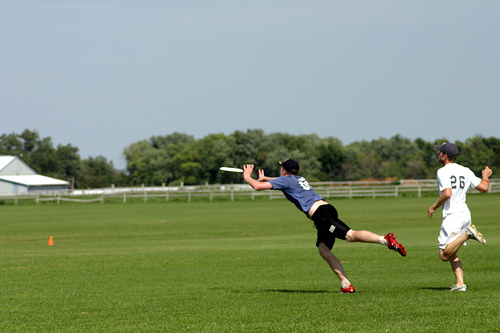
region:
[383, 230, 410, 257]
the shoe is off the ground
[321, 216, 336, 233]
the shorts are black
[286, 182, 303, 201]
the shirt is blue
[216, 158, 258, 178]
he is reaching for the frisbee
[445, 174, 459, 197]
the shirt is white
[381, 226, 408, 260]
the shoe is red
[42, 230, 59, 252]
the cone is orange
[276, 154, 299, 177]
he is wearing a hat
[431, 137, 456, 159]
the hat is gray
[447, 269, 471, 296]
he is standing on one leg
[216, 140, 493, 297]
two men playing frisbee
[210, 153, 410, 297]
a man reaching out to catch a frisbee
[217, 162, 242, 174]
a white frisbee in the air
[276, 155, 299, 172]
a black baseball cap on the man's head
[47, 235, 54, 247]
an orange cone in the field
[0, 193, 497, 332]
a large field of green grass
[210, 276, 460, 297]
the men's shadows in the grass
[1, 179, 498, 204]
a wooden fence behind the field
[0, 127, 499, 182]
a line of trees in the distance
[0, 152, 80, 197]
a white building behind the fence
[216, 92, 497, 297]
people playing frisbee on lawn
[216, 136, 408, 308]
person catching the frisbee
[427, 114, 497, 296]
person running after person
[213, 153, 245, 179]
frisbee in the air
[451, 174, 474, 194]
numbering on shirt of man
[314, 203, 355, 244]
shorts on a man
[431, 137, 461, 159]
hat on a man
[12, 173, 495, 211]
fence surrounding an area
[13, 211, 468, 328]
green space to play on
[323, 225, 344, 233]
logo on shorts on man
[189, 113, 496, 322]
two mean playing ultimate frisbee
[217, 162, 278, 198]
two hands catching a frisbee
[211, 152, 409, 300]
a man catching a frisbee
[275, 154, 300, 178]
the head of a man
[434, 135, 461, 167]
the head of a man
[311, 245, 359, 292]
the leg of a man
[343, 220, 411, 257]
the leg of a man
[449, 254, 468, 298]
the leg of a man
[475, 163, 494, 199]
the arm of a man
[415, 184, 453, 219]
the arm of a man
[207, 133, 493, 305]
two men playing ultimate frisbee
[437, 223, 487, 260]
the leg of a man